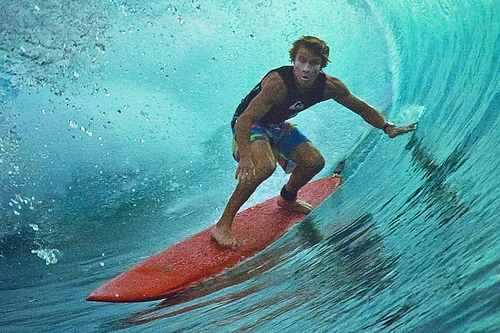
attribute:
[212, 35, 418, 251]
man — surfer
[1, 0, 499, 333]
wave — blue, in ocean, large, curving, glassy-like, in water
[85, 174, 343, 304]
surfboard — red, top up, in water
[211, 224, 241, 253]
foot — bare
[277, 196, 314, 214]
foot — bare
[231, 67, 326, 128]
shirt — blue, sleeveless, black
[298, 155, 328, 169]
knee — bent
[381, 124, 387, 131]
strap — black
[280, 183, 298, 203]
ankle band — black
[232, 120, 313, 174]
swim trunks — blue, partially green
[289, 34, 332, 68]
hair — blonde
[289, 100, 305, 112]
design — black, white